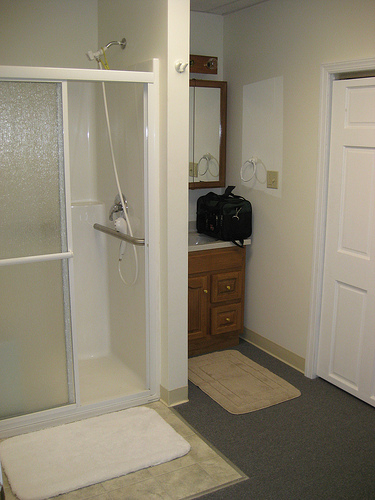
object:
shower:
[0, 3, 169, 440]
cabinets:
[185, 245, 248, 360]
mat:
[188, 344, 303, 414]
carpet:
[255, 413, 373, 499]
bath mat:
[0, 403, 194, 498]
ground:
[276, 155, 293, 172]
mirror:
[188, 78, 228, 189]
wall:
[226, 10, 362, 33]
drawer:
[207, 268, 245, 303]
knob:
[224, 283, 233, 291]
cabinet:
[183, 71, 231, 190]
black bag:
[195, 182, 254, 249]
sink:
[186, 230, 213, 243]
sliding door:
[1, 79, 79, 429]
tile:
[154, 473, 216, 495]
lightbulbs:
[189, 57, 195, 71]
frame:
[0, 55, 373, 441]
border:
[220, 81, 227, 183]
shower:
[73, 34, 149, 245]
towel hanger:
[174, 60, 192, 77]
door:
[317, 74, 373, 398]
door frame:
[301, 56, 373, 381]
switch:
[260, 161, 294, 190]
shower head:
[112, 214, 128, 261]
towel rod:
[237, 157, 257, 184]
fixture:
[189, 53, 218, 76]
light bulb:
[204, 57, 218, 69]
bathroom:
[0, 0, 375, 498]